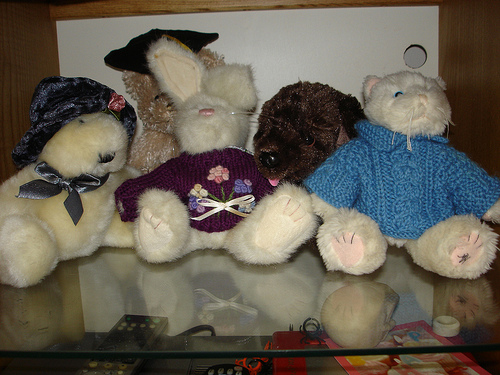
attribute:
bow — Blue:
[0, 161, 117, 212]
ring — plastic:
[299, 315, 320, 338]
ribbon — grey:
[16, 162, 113, 222]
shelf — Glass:
[0, 235, 499, 359]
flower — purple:
[233, 177, 253, 193]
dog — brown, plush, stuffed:
[248, 77, 365, 184]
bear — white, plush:
[15, 78, 151, 257]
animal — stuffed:
[7, 78, 145, 284]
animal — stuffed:
[117, 31, 222, 176]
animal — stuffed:
[129, 34, 314, 273]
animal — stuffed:
[252, 70, 364, 171]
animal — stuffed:
[309, 59, 498, 288]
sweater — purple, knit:
[113, 147, 278, 232]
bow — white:
[188, 192, 255, 221]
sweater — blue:
[307, 120, 499, 235]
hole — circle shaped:
[401, 40, 430, 72]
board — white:
[53, 3, 439, 336]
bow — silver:
[10, 157, 109, 223]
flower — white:
[188, 182, 208, 201]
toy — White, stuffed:
[303, 62, 498, 282]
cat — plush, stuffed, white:
[310, 71, 499, 280]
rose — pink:
[104, 87, 131, 111]